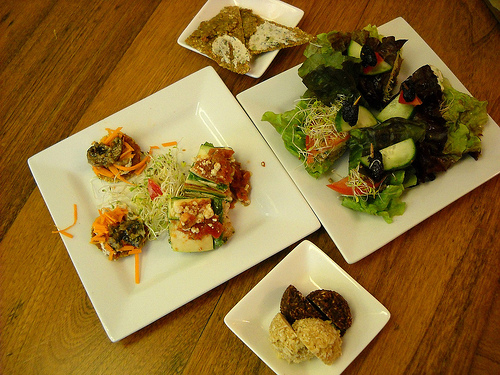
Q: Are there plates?
A: Yes, there is a plate.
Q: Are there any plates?
A: Yes, there is a plate.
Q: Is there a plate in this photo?
A: Yes, there is a plate.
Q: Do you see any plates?
A: Yes, there is a plate.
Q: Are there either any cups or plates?
A: Yes, there is a plate.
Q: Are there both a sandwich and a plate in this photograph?
A: Yes, there are both a plate and a sandwich.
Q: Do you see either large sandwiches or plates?
A: Yes, there is a large plate.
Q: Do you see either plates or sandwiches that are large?
A: Yes, the plate is large.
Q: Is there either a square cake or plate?
A: Yes, there is a square plate.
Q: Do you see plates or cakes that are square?
A: Yes, the plate is square.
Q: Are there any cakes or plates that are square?
A: Yes, the plate is square.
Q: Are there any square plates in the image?
A: Yes, there is a square plate.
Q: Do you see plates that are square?
A: Yes, there is a plate that is square.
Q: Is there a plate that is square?
A: Yes, there is a plate that is square.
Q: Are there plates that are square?
A: Yes, there is a plate that is square.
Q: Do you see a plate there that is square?
A: Yes, there is a plate that is square.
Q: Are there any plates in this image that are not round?
A: Yes, there is a square plate.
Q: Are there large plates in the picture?
A: Yes, there is a large plate.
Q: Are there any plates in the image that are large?
A: Yes, there is a plate that is large.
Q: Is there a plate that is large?
A: Yes, there is a plate that is large.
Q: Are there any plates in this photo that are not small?
A: Yes, there is a large plate.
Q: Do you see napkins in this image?
A: No, there are no napkins.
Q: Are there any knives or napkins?
A: No, there are no napkins or knives.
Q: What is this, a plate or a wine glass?
A: This is a plate.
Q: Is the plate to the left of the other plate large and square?
A: Yes, the plate is large and square.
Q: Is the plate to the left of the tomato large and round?
A: No, the plate is large but square.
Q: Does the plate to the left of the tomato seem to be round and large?
A: No, the plate is large but square.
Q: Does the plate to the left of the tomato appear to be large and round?
A: No, the plate is large but square.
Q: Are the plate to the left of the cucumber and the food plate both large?
A: Yes, both the plate and the plate are large.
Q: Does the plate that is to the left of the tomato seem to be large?
A: Yes, the plate is large.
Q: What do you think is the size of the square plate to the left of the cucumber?
A: The plate is large.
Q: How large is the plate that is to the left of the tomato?
A: The plate is large.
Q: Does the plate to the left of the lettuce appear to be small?
A: No, the plate is large.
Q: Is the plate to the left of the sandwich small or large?
A: The plate is large.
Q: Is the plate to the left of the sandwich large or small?
A: The plate is large.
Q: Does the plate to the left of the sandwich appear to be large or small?
A: The plate is large.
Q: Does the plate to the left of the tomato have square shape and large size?
A: Yes, the plate is square and large.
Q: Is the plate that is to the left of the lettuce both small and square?
A: No, the plate is square but large.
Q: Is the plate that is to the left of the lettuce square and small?
A: No, the plate is square but large.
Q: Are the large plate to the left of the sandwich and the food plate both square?
A: Yes, both the plate and the plate are square.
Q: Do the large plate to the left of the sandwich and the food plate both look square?
A: Yes, both the plate and the plate are square.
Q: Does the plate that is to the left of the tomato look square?
A: Yes, the plate is square.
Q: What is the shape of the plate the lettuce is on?
A: The plate is square.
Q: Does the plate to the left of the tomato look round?
A: No, the plate is square.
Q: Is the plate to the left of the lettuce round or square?
A: The plate is square.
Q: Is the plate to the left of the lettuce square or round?
A: The plate is square.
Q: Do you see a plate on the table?
A: Yes, there is a plate on the table.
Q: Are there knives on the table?
A: No, there is a plate on the table.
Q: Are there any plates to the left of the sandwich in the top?
A: Yes, there is a plate to the left of the sandwich.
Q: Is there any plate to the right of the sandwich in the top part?
A: No, the plate is to the left of the sandwich.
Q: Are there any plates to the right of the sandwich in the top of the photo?
A: No, the plate is to the left of the sandwich.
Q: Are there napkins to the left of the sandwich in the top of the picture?
A: No, there is a plate to the left of the sandwich.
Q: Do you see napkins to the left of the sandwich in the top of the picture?
A: No, there is a plate to the left of the sandwich.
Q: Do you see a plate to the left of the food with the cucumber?
A: Yes, there is a plate to the left of the food.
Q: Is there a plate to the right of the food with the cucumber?
A: No, the plate is to the left of the food.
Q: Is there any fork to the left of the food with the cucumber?
A: No, there is a plate to the left of the food.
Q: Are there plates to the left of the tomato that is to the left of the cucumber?
A: Yes, there is a plate to the left of the tomato.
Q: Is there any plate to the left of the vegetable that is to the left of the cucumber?
A: Yes, there is a plate to the left of the tomato.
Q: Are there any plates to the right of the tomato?
A: No, the plate is to the left of the tomato.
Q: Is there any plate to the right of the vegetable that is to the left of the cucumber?
A: No, the plate is to the left of the tomato.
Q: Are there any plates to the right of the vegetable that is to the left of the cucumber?
A: No, the plate is to the left of the tomato.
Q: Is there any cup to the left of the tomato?
A: No, there is a plate to the left of the tomato.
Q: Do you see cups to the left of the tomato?
A: No, there is a plate to the left of the tomato.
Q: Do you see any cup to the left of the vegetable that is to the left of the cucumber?
A: No, there is a plate to the left of the tomato.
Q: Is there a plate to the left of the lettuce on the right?
A: Yes, there is a plate to the left of the lettuce.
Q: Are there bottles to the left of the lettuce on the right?
A: No, there is a plate to the left of the lettuce.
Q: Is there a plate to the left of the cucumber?
A: Yes, there is a plate to the left of the cucumber.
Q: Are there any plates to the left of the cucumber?
A: Yes, there is a plate to the left of the cucumber.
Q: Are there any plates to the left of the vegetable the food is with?
A: Yes, there is a plate to the left of the cucumber.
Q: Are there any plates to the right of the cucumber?
A: No, the plate is to the left of the cucumber.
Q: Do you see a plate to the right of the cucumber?
A: No, the plate is to the left of the cucumber.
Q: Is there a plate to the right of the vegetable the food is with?
A: No, the plate is to the left of the cucumber.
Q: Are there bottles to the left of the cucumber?
A: No, there is a plate to the left of the cucumber.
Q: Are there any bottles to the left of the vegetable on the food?
A: No, there is a plate to the left of the cucumber.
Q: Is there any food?
A: Yes, there is food.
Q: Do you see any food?
A: Yes, there is food.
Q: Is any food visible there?
A: Yes, there is food.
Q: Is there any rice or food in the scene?
A: Yes, there is food.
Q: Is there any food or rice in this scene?
A: Yes, there is food.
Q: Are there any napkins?
A: No, there are no napkins.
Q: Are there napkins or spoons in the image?
A: No, there are no napkins or spoons.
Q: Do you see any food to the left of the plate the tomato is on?
A: Yes, there is food to the left of the plate.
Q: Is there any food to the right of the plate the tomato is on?
A: No, the food is to the left of the plate.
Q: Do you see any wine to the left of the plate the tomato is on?
A: No, there is food to the left of the plate.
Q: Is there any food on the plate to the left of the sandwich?
A: Yes, there is food on the plate.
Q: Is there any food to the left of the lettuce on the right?
A: Yes, there is food to the left of the lettuce.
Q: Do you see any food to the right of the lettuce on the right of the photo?
A: No, the food is to the left of the lettuce.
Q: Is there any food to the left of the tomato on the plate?
A: Yes, there is food to the left of the tomato.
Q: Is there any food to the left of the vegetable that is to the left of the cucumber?
A: Yes, there is food to the left of the tomato.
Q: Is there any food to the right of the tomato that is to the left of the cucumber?
A: No, the food is to the left of the tomato.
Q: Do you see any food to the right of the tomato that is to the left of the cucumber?
A: No, the food is to the left of the tomato.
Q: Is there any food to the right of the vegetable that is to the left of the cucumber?
A: No, the food is to the left of the tomato.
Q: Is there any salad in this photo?
A: Yes, there is salad.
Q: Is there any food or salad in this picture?
A: Yes, there is salad.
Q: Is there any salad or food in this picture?
A: Yes, there is salad.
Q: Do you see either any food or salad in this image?
A: Yes, there is salad.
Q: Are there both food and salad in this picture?
A: Yes, there are both salad and food.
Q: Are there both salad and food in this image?
A: Yes, there are both salad and food.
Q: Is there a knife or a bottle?
A: No, there are no knives or bottles.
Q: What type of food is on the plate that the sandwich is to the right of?
A: The food is salad.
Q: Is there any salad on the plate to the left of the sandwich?
A: Yes, there is salad on the plate.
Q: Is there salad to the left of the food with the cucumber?
A: Yes, there is salad to the left of the food.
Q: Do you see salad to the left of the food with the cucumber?
A: Yes, there is salad to the left of the food.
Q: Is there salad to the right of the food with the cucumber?
A: No, the salad is to the left of the food.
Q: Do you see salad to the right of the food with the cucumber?
A: No, the salad is to the left of the food.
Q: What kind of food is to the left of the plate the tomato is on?
A: The food is salad.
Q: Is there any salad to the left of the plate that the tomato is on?
A: Yes, there is salad to the left of the plate.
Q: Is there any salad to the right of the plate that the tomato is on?
A: No, the salad is to the left of the plate.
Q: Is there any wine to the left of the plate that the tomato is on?
A: No, there is salad to the left of the plate.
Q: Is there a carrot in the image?
A: Yes, there is a carrot.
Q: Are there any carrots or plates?
A: Yes, there is a carrot.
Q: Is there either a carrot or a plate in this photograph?
A: Yes, there is a carrot.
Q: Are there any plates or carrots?
A: Yes, there is a carrot.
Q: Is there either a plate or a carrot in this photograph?
A: Yes, there is a carrot.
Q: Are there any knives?
A: No, there are no knives.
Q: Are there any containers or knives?
A: No, there are no knives or containers.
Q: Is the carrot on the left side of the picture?
A: Yes, the carrot is on the left of the image.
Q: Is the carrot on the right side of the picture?
A: No, the carrot is on the left of the image.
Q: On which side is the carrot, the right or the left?
A: The carrot is on the left of the image.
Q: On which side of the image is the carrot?
A: The carrot is on the left of the image.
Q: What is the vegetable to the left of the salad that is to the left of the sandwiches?
A: The vegetable is a carrot.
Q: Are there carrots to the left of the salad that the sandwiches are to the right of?
A: Yes, there is a carrot to the left of the salad.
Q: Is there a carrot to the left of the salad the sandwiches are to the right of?
A: Yes, there is a carrot to the left of the salad.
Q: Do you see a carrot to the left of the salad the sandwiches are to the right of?
A: Yes, there is a carrot to the left of the salad.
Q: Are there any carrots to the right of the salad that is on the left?
A: No, the carrot is to the left of the salad.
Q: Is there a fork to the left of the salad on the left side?
A: No, there is a carrot to the left of the salad.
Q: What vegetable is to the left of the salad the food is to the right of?
A: The vegetable is a carrot.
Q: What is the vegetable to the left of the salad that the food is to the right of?
A: The vegetable is a carrot.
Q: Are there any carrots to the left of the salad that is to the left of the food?
A: Yes, there is a carrot to the left of the salad.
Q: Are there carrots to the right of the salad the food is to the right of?
A: No, the carrot is to the left of the salad.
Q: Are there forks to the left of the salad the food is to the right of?
A: No, there is a carrot to the left of the salad.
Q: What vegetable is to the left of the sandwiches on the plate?
A: The vegetable is a carrot.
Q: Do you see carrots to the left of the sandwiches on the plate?
A: Yes, there is a carrot to the left of the sandwiches.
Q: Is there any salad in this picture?
A: Yes, there is salad.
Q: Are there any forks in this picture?
A: No, there are no forks.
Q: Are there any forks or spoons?
A: No, there are no forks or spoons.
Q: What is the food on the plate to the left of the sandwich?
A: The food is salad.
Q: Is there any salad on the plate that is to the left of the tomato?
A: Yes, there is salad on the plate.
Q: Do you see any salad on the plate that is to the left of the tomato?
A: Yes, there is salad on the plate.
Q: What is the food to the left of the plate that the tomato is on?
A: The food is salad.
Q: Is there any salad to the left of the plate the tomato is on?
A: Yes, there is salad to the left of the plate.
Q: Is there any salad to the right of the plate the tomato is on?
A: No, the salad is to the left of the plate.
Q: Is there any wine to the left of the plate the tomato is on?
A: No, there is salad to the left of the plate.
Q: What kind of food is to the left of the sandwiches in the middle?
A: The food is salad.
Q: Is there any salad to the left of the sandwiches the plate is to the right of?
A: Yes, there is salad to the left of the sandwiches.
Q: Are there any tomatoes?
A: Yes, there is a tomato.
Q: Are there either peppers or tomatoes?
A: Yes, there is a tomato.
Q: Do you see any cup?
A: No, there are no cups.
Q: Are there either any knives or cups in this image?
A: No, there are no cups or knives.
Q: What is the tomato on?
A: The tomato is on the plate.